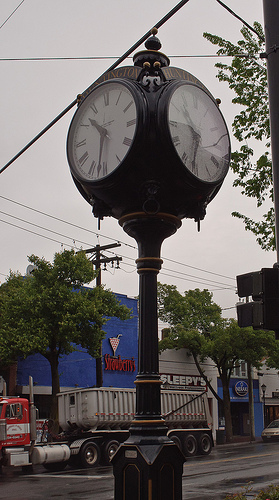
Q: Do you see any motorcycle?
A: No, there are no motorcycles.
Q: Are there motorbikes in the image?
A: No, there are no motorbikes.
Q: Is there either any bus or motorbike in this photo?
A: No, there are no motorcycles or buses.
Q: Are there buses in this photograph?
A: No, there are no buses.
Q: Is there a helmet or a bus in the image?
A: No, there are no buses or helmets.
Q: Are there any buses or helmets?
A: No, there are no buses or helmets.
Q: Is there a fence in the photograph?
A: No, there are no fences.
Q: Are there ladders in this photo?
A: No, there are no ladders.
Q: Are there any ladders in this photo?
A: No, there are no ladders.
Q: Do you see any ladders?
A: No, there are no ladders.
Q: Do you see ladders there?
A: No, there are no ladders.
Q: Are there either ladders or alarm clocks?
A: No, there are no ladders or alarm clocks.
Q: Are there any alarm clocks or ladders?
A: No, there are no ladders or alarm clocks.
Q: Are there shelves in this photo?
A: No, there are no shelves.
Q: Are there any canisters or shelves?
A: No, there are no shelves or canisters.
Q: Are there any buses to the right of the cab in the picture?
A: No, there is a box to the right of the cab.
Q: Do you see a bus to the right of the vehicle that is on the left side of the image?
A: No, there is a box to the right of the cab.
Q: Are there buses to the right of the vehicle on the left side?
A: No, there is a box to the right of the cab.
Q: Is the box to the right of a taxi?
A: Yes, the box is to the right of a taxi.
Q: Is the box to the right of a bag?
A: No, the box is to the right of a taxi.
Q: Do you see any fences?
A: No, there are no fences.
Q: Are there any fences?
A: No, there are no fences.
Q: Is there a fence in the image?
A: No, there are no fences.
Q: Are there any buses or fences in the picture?
A: No, there are no fences or buses.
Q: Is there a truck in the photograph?
A: Yes, there is a truck.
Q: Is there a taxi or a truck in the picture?
A: Yes, there is a truck.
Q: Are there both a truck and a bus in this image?
A: No, there is a truck but no buses.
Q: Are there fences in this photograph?
A: No, there are no fences.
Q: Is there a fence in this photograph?
A: No, there are no fences.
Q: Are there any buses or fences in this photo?
A: No, there are no fences or buses.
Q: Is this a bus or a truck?
A: This is a truck.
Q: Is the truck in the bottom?
A: Yes, the truck is in the bottom of the image.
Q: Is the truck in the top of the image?
A: No, the truck is in the bottom of the image.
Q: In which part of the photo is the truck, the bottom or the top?
A: The truck is in the bottom of the image.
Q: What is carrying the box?
A: The truck is carrying the box.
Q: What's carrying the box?
A: The truck is carrying the box.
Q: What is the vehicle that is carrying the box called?
A: The vehicle is a truck.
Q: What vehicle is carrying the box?
A: The vehicle is a truck.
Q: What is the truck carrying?
A: The truck is carrying a box.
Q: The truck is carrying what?
A: The truck is carrying a box.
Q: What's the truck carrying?
A: The truck is carrying a box.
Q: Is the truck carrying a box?
A: Yes, the truck is carrying a box.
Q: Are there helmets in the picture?
A: No, there are no helmets.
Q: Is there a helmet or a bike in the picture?
A: No, there are no helmets or bikes.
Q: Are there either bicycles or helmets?
A: No, there are no helmets or bicycles.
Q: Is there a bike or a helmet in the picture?
A: No, there are no helmets or bikes.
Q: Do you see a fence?
A: No, there are no fences.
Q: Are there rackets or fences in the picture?
A: No, there are no fences or rackets.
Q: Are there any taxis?
A: Yes, there is a taxi.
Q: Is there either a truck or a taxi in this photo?
A: Yes, there is a taxi.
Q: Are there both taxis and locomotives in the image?
A: No, there is a taxi but no locomotives.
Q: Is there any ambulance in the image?
A: No, there are no ambulances.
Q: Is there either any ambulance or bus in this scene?
A: No, there are no ambulances or buses.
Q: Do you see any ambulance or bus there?
A: No, there are no ambulances or buses.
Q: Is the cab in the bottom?
A: Yes, the cab is in the bottom of the image.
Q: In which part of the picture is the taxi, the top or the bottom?
A: The taxi is in the bottom of the image.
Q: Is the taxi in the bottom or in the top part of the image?
A: The taxi is in the bottom of the image.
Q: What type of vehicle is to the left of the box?
A: The vehicle is a taxi.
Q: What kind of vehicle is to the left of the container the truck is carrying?
A: The vehicle is a taxi.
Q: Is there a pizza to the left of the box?
A: No, there is a taxi to the left of the box.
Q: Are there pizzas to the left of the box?
A: No, there is a taxi to the left of the box.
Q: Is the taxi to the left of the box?
A: Yes, the taxi is to the left of the box.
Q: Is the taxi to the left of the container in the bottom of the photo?
A: Yes, the taxi is to the left of the box.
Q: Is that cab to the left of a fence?
A: No, the cab is to the left of the box.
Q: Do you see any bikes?
A: No, there are no bikes.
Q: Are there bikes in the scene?
A: No, there are no bikes.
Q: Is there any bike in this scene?
A: No, there are no bikes.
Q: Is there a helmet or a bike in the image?
A: No, there are no bikes or helmets.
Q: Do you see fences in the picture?
A: No, there are no fences.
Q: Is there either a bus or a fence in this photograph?
A: No, there are no fences or buses.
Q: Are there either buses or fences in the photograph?
A: No, there are no fences or buses.